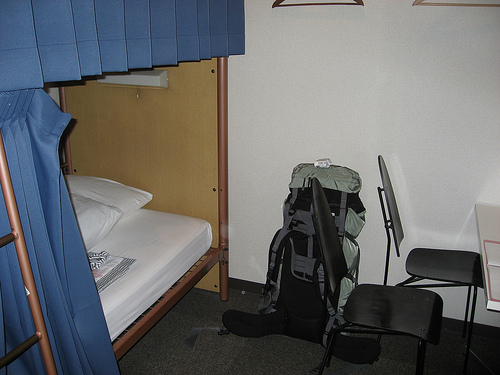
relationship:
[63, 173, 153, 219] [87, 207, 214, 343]
pillow laying on bed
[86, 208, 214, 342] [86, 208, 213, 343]
mattress has sheet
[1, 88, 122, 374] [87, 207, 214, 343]
drape covering bed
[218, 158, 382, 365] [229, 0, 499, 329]
backpack next to wall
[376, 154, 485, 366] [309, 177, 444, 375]
chair next to chair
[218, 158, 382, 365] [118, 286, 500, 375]
backpack sitting on floor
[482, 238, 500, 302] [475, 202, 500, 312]
notebook sitting on desk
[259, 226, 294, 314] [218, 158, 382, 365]
strap attached on backpack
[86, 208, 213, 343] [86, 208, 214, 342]
sheet wrapped on mattress